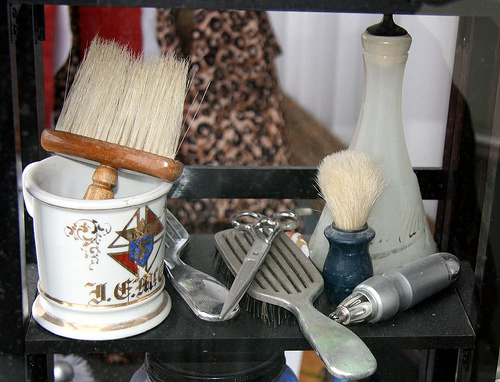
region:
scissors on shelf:
[217, 208, 297, 319]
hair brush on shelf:
[207, 225, 374, 375]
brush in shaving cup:
[39, 35, 191, 200]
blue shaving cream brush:
[314, 146, 384, 301]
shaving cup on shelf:
[19, 150, 176, 342]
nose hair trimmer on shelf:
[327, 248, 462, 328]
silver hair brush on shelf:
[156, 206, 243, 327]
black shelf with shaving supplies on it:
[23, 230, 476, 379]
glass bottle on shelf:
[310, 15, 450, 299]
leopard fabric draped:
[165, 10, 299, 223]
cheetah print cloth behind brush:
[52, 9, 302, 221]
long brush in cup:
[41, 25, 190, 200]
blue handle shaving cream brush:
[311, 150, 386, 307]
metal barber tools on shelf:
[158, 207, 461, 380]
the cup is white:
[9, 153, 174, 341]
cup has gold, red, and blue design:
[32, 204, 175, 311]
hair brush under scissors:
[211, 221, 376, 379]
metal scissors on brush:
[217, 208, 300, 319]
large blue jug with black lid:
[128, 348, 298, 380]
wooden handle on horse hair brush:
[37, 35, 182, 199]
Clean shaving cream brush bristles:
[315, 145, 386, 229]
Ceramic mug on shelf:
[13, 155, 175, 338]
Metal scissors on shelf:
[208, 205, 302, 320]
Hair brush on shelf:
[210, 223, 380, 380]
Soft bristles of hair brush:
[206, 245, 328, 326]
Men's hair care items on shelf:
[21, 12, 465, 377]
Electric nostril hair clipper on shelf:
[322, 250, 460, 327]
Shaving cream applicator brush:
[318, 150, 388, 307]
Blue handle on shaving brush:
[317, 225, 377, 302]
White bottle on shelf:
[300, 29, 435, 276]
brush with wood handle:
[48, 28, 186, 176]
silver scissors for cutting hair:
[207, 197, 279, 341]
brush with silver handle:
[213, 202, 376, 374]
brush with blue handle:
[307, 138, 369, 288]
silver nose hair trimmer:
[332, 239, 469, 347]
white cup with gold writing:
[18, 155, 175, 330]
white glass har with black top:
[329, 23, 447, 266]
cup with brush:
[26, 25, 193, 325]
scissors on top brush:
[207, 190, 289, 318]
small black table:
[26, 218, 465, 360]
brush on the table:
[310, 154, 382, 285]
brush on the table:
[50, 20, 201, 191]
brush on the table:
[208, 212, 335, 338]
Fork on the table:
[160, 207, 240, 347]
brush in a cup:
[20, 38, 202, 334]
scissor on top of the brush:
[201, 182, 303, 319]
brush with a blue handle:
[316, 210, 375, 290]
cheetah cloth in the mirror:
[161, 15, 301, 167]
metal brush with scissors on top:
[221, 200, 376, 380]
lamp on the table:
[357, 30, 433, 263]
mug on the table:
[35, 193, 157, 331]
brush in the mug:
[51, 51, 178, 203]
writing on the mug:
[63, 265, 149, 294]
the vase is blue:
[332, 267, 365, 289]